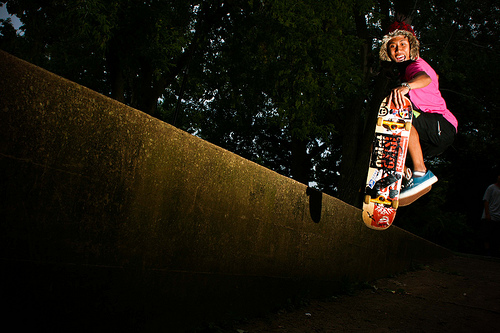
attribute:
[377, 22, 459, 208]
skateboarder — smiling, performing a trick, skateboarding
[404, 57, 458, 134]
shirt — pink, short-sleeved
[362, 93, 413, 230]
skateboard — decorated, brightly patterned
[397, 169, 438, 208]
shoes — blue, teal, white, canvas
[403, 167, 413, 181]
laces — white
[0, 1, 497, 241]
trees — big, green, dark green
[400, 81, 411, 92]
watch — silver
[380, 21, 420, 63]
hat — red, fake, fur-lined, fur, brown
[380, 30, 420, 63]
trim — fuzzy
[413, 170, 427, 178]
sock — white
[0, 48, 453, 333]
wall — cement, concrete, gray, grey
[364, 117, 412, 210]
wheels — yellow, brown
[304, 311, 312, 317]
trash — white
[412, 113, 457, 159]
shorts — black